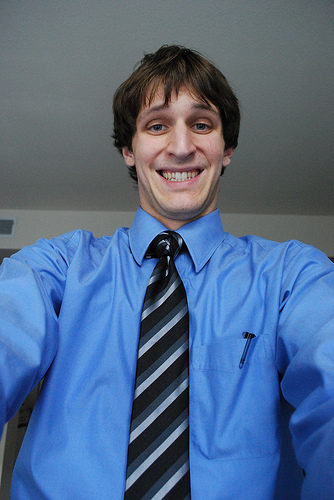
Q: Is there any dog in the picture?
A: No, there are no dogs.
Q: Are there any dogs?
A: No, there are no dogs.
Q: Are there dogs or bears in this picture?
A: No, there are no dogs or bears.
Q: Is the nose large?
A: Yes, the nose is large.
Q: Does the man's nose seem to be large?
A: Yes, the nose is large.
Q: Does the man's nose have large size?
A: Yes, the nose is large.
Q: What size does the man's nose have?
A: The nose has large size.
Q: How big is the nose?
A: The nose is large.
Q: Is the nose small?
A: No, the nose is large.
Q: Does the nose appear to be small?
A: No, the nose is large.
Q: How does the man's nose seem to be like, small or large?
A: The nose is large.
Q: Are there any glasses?
A: No, there are no glasses.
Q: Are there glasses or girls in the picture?
A: No, there are no glasses or girls.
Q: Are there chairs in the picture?
A: No, there are no chairs.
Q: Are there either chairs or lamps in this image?
A: No, there are no chairs or lamps.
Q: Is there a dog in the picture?
A: No, there are no dogs.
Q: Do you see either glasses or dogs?
A: No, there are no dogs or glasses.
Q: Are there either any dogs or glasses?
A: No, there are no dogs or glasses.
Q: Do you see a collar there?
A: Yes, there is a collar.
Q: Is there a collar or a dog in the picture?
A: Yes, there is a collar.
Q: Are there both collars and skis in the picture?
A: No, there is a collar but no skis.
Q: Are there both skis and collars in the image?
A: No, there is a collar but no skis.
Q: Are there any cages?
A: No, there are no cages.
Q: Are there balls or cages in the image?
A: No, there are no cages or balls.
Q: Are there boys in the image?
A: No, there are no boys.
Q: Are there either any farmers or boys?
A: No, there are no boys or farmers.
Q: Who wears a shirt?
A: The man wears a shirt.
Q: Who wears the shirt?
A: The man wears a shirt.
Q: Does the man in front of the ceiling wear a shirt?
A: Yes, the man wears a shirt.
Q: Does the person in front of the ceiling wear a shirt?
A: Yes, the man wears a shirt.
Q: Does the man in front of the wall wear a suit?
A: No, the man wears a shirt.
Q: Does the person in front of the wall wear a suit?
A: No, the man wears a shirt.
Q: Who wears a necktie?
A: The man wears a necktie.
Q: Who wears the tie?
A: The man wears a necktie.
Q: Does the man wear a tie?
A: Yes, the man wears a tie.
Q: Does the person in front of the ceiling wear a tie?
A: Yes, the man wears a tie.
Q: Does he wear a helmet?
A: No, the man wears a tie.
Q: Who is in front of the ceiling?
A: The man is in front of the ceiling.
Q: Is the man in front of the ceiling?
A: Yes, the man is in front of the ceiling.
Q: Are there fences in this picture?
A: No, there are no fences.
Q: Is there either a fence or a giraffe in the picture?
A: No, there are no fences or giraffes.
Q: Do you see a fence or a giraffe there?
A: No, there are no fences or giraffes.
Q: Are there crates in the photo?
A: No, there are no crates.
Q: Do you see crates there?
A: No, there are no crates.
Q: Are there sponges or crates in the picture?
A: No, there are no crates or sponges.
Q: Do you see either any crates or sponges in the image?
A: No, there are no crates or sponges.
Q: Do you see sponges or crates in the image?
A: No, there are no crates or sponges.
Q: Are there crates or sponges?
A: No, there are no crates or sponges.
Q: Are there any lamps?
A: No, there are no lamps.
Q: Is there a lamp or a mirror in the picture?
A: No, there are no lamps or mirrors.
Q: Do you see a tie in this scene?
A: Yes, there is a tie.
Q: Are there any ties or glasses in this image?
A: Yes, there is a tie.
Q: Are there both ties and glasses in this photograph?
A: No, there is a tie but no glasses.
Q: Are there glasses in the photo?
A: No, there are no glasses.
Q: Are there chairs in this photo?
A: No, there are no chairs.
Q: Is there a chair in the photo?
A: No, there are no chairs.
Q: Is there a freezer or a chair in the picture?
A: No, there are no chairs or refrigerators.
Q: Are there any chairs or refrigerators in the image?
A: No, there are no chairs or refrigerators.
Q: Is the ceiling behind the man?
A: Yes, the ceiling is behind the man.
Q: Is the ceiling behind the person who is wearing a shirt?
A: Yes, the ceiling is behind the man.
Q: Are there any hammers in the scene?
A: No, there are no hammers.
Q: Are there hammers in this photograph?
A: No, there are no hammers.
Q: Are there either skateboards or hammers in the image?
A: No, there are no hammers or skateboards.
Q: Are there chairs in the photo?
A: No, there are no chairs.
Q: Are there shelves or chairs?
A: No, there are no chairs or shelves.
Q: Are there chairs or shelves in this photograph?
A: No, there are no chairs or shelves.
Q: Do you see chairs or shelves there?
A: No, there are no chairs or shelves.